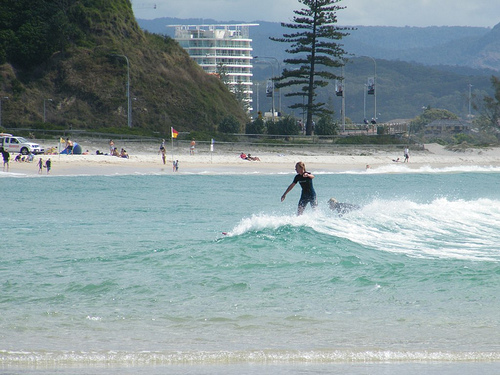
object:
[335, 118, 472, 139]
building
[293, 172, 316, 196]
top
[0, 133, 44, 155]
truck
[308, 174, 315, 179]
arm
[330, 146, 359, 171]
ground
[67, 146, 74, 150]
shorts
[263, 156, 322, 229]
person water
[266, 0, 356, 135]
evergreen tree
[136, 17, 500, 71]
mountain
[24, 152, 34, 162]
person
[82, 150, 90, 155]
person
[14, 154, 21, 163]
person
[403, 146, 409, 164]
person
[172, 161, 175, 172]
person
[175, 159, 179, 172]
person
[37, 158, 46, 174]
person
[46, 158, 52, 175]
person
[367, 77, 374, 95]
signs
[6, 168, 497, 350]
ocean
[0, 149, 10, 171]
person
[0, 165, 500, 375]
wave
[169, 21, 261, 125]
building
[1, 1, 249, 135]
hill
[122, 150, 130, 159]
people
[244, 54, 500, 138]
mountains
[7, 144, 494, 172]
sand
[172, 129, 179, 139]
flag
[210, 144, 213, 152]
sign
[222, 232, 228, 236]
surfboard tip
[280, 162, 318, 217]
girl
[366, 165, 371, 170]
person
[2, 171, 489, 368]
water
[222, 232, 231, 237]
surfboard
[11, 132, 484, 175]
beach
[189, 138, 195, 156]
male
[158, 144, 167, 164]
lady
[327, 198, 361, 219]
guy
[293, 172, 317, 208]
wetsuit